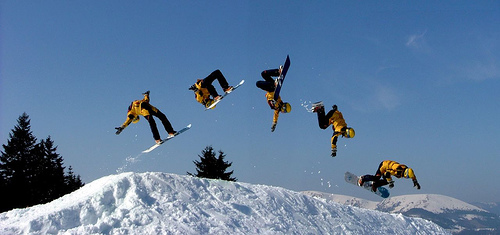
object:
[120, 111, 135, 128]
arm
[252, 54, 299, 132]
person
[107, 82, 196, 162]
he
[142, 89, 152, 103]
arm